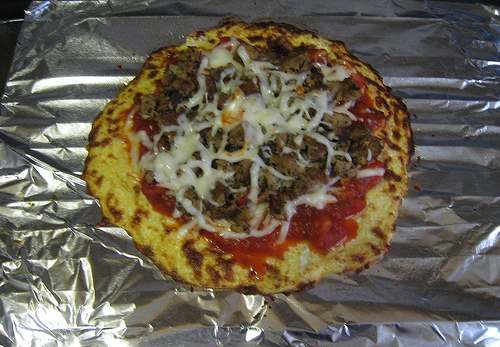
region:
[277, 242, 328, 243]
Red pasta sauce on top of pizza.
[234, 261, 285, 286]
Red pasta sauce on top of pizza.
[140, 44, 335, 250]
cheese on top of the pizza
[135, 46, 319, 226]
cheese on top of the pizza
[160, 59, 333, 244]
cheese on top of the pizza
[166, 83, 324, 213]
cheese on top of the pizza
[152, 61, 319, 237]
cheese on top of the pizza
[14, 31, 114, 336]
the foil is silver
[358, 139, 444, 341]
the foil is silver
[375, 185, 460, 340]
the foil is silver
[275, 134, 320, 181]
Big pizza with shredded pieces of cheese on it.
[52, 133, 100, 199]
Big pizza with shredded pieces of cheese on it.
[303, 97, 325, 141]
Big pizza with shredded pieces of cheese on it.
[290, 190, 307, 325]
Big pizza with shredded pieces of cheese on it.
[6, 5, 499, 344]
pizza sitting on tin foil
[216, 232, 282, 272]
red sauce sticking out of the cheese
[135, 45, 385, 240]
white cheese on top of the pizza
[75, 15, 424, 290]
thick crust around the circumference of the pizza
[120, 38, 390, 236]
ground meat on top of the pizza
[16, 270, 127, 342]
light shining on the foil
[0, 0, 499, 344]
wrinkles on the foil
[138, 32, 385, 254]
cheese on top of the pizza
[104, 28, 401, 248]
ground meat mixed in with cheese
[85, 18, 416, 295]
Pizza sitting on top of foil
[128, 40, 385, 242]
Melted cheese on top of pizza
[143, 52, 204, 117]
Cooked beef on top of pizza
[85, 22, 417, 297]
Pizza with toppings on top of foil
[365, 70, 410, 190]
Browned edge of pizza crust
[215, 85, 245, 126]
Browned cheese on top of pizza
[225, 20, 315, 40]
Burnt edge on side of pizza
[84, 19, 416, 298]
a small home made pizza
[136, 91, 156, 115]
a small ball of meat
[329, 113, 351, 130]
a small ball of meat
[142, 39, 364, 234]
melted, shredded white cheese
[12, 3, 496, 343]
a large piece of tin foil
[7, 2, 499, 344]
a large piece of aluminum foil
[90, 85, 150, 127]
red sauce cheese and meat on pizza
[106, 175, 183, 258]
red sauce cheese and meat on pizza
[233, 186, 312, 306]
red sauce cheese and meat on pizza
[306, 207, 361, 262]
red sauce cheese and meat on pizza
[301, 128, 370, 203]
red sauce cheese and meat on pizza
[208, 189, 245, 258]
red sauce cheese and meat on pizza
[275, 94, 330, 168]
red sauce cheese and meat on pizza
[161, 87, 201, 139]
red sauce cheese and meat on pizza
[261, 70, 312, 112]
red sauce cheese and meat on pizza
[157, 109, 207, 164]
red sauce cheese and meat on pizza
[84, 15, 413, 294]
whole pizza pie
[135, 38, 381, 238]
mozzerella cheese on a pizza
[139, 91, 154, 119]
piece of gound beef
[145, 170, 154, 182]
piece of gound beef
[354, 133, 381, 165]
piece of gound beef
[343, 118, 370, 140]
piece of gound beef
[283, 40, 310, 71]
piece of gound beef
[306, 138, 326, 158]
piece of gound beef